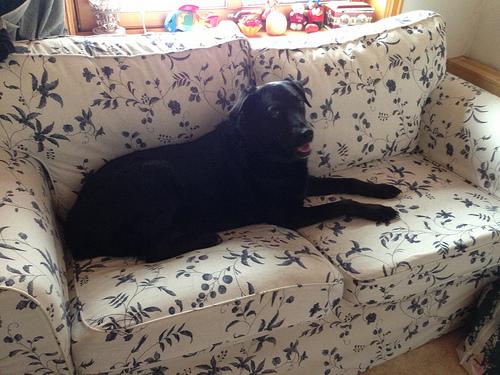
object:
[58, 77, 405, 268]
dog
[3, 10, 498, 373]
sofa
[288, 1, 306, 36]
toys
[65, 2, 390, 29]
window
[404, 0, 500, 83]
wall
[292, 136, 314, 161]
mouth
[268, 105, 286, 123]
eyes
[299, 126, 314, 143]
nose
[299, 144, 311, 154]
tongue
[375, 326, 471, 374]
carpet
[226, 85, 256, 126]
ears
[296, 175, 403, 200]
legs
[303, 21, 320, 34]
tomato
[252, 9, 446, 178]
cushion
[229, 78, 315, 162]
head